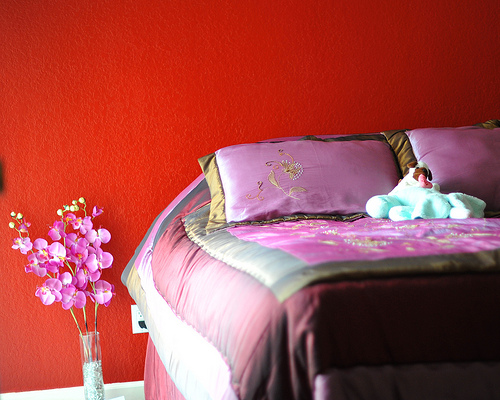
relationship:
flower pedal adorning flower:
[34, 286, 49, 298] [31, 279, 68, 307]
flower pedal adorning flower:
[58, 285, 77, 305] [56, 280, 87, 310]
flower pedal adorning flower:
[72, 290, 86, 310] [57, 284, 87, 310]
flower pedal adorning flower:
[58, 270, 75, 287] [57, 270, 80, 291]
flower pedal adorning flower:
[47, 241, 67, 261] [43, 240, 66, 268]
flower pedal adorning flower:
[78, 216, 92, 235] [70, 216, 93, 234]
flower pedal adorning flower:
[96, 251, 113, 269] [83, 245, 113, 272]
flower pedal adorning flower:
[94, 280, 111, 295] [88, 276, 116, 306]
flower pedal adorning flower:
[46, 227, 62, 243] [45, 219, 67, 240]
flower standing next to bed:
[10, 234, 33, 254] [120, 116, 483, 398]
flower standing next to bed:
[31, 279, 68, 307] [120, 116, 483, 398]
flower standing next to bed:
[56, 280, 87, 310] [120, 116, 483, 398]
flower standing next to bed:
[88, 276, 116, 306] [120, 116, 483, 398]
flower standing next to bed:
[80, 247, 113, 272] [120, 116, 483, 398]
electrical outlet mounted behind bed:
[129, 301, 150, 334] [120, 116, 483, 398]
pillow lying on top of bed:
[195, 130, 400, 234] [120, 116, 483, 398]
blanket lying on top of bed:
[119, 170, 484, 396] [120, 116, 483, 398]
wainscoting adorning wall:
[0, 378, 143, 398] [1, 1, 484, 391]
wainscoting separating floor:
[0, 378, 143, 398] [102, 385, 145, 398]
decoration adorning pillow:
[245, 145, 307, 203] [195, 130, 400, 234]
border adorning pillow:
[195, 131, 389, 232] [195, 130, 400, 234]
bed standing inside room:
[120, 116, 483, 398] [1, 0, 484, 395]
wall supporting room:
[1, 1, 484, 391] [1, 0, 484, 395]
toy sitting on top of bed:
[366, 164, 486, 222] [120, 116, 483, 398]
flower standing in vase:
[45, 220, 67, 242] [78, 329, 105, 399]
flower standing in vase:
[69, 212, 93, 235] [78, 329, 105, 399]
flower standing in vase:
[80, 247, 113, 272] [78, 329, 105, 399]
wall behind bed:
[1, 1, 484, 391] [120, 116, 483, 398]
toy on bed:
[366, 164, 486, 222] [120, 116, 483, 398]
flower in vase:
[56, 280, 87, 310] [78, 329, 105, 399]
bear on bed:
[367, 160, 488, 219] [120, 116, 483, 398]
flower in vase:
[31, 279, 68, 307] [77, 330, 107, 399]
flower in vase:
[85, 278, 115, 330] [78, 329, 105, 399]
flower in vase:
[69, 248, 98, 286] [77, 330, 107, 399]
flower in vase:
[87, 226, 110, 252] [77, 330, 107, 399]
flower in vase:
[32, 237, 50, 256] [77, 330, 107, 399]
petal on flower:
[98, 226, 110, 244] [84, 226, 110, 250]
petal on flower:
[84, 229, 97, 244] [77, 216, 96, 241]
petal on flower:
[79, 217, 92, 235] [73, 212, 91, 234]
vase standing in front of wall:
[78, 329, 105, 399] [1, 1, 484, 391]